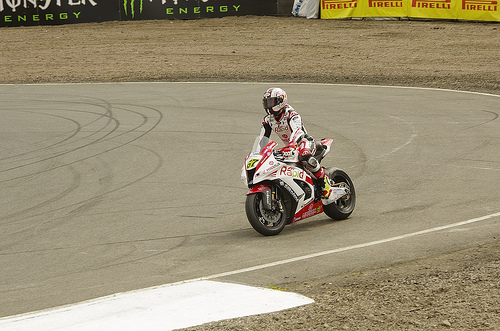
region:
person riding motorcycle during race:
[231, 80, 353, 232]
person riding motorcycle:
[242, 81, 360, 233]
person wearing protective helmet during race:
[257, 85, 292, 110]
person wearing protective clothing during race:
[263, 119, 313, 154]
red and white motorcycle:
[245, 153, 315, 226]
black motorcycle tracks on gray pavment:
[17, 90, 85, 155]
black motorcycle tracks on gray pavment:
[15, 167, 71, 194]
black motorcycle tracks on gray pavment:
[86, 148, 148, 185]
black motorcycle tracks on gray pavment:
[124, 96, 166, 136]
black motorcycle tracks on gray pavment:
[72, 90, 122, 139]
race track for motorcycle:
[109, 131, 184, 171]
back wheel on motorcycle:
[330, 176, 362, 213]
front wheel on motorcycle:
[249, 197, 290, 232]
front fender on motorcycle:
[248, 184, 265, 193]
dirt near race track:
[92, 33, 239, 65]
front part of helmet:
[265, 86, 284, 94]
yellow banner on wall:
[322, 2, 394, 17]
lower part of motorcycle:
[301, 202, 319, 214]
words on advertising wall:
[145, 0, 258, 16]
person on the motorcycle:
[204, 75, 371, 227]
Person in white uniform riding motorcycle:
[194, 70, 354, 243]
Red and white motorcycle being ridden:
[231, 129, 353, 233]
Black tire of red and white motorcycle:
[243, 175, 296, 232]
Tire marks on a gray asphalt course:
[30, 87, 170, 157]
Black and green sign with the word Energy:
[100, 0, 282, 14]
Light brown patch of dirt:
[103, 30, 391, 67]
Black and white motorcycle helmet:
[246, 79, 291, 111]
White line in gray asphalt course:
[239, 247, 334, 282]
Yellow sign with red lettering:
[398, 0, 460, 29]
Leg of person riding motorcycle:
[303, 148, 333, 195]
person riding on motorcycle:
[227, 84, 367, 241]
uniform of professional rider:
[259, 111, 325, 176]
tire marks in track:
[59, 95, 164, 197]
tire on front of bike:
[238, 194, 287, 241]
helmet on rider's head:
[259, 81, 294, 118]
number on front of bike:
[244, 156, 265, 178]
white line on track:
[377, 216, 452, 252]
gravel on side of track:
[380, 249, 484, 327]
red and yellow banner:
[319, 2, 472, 24]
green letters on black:
[158, 1, 246, 23]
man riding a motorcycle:
[192, 46, 383, 251]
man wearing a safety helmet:
[166, 68, 364, 255]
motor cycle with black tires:
[190, 151, 395, 248]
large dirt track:
[10, 92, 441, 238]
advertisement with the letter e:
[156, 0, 253, 25]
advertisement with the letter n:
[158, 0, 254, 21]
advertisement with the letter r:
[152, 0, 247, 25]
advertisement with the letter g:
[151, 0, 247, 20]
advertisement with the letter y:
[152, 2, 248, 32]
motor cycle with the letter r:
[175, 76, 375, 247]